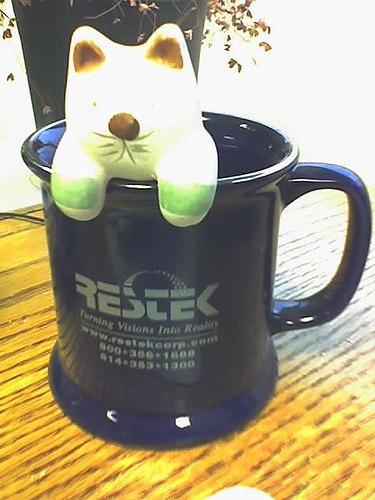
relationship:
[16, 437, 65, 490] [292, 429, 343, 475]
wooden surface with lines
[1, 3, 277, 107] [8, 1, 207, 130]
leaves hanging over black vase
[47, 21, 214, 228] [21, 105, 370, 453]
cat in coffee mug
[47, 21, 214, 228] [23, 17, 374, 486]
cat in cup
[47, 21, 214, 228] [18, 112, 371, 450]
cat in coffee mug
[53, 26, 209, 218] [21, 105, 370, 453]
cat in coffee mug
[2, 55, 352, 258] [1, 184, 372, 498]
coffee mug on table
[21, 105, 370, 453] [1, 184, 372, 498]
coffee mug on table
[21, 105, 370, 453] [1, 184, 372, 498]
coffee mug over table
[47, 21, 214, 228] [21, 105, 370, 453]
cat inside coffee mug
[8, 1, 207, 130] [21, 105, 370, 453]
black vase behind coffee mug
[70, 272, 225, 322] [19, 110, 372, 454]
large letters on gray mug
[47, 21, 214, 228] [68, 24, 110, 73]
cat with cat ears